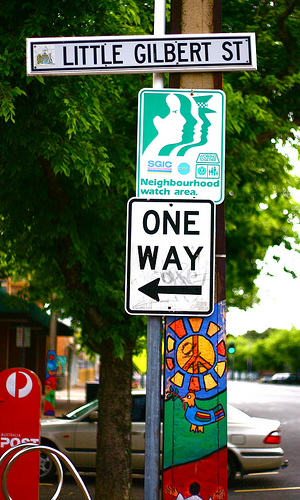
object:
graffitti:
[126, 198, 214, 314]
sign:
[0, 367, 42, 499]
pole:
[144, 315, 163, 499]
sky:
[226, 129, 299, 335]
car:
[39, 373, 288, 492]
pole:
[162, 0, 226, 497]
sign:
[176, 334, 215, 375]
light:
[264, 430, 282, 444]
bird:
[182, 389, 225, 433]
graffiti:
[163, 299, 227, 500]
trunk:
[95, 335, 134, 500]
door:
[78, 395, 164, 473]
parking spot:
[28, 374, 291, 500]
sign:
[16, 326, 32, 348]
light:
[227, 342, 236, 355]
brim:
[193, 89, 213, 95]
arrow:
[138, 277, 203, 302]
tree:
[0, 0, 300, 500]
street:
[38, 382, 300, 500]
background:
[0, 0, 300, 388]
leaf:
[0, 0, 300, 359]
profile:
[142, 91, 217, 156]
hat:
[192, 95, 217, 114]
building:
[0, 271, 95, 395]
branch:
[166, 391, 186, 412]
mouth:
[182, 398, 187, 403]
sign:
[26, 32, 258, 77]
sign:
[136, 87, 227, 205]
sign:
[124, 196, 216, 318]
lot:
[38, 466, 297, 500]